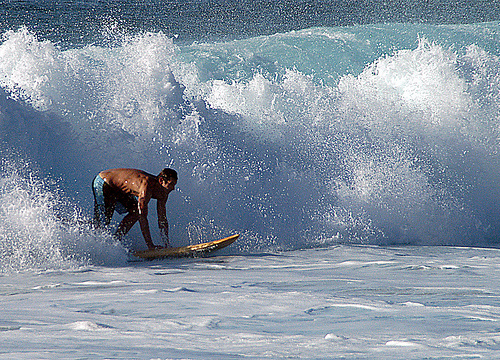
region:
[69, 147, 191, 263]
surfer in black and blue shorts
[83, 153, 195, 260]
a shirtless man surfing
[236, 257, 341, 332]
white ocean foam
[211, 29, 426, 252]
a wave in the ocean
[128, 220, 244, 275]
a tan colored surfboard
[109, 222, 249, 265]
a surfer with his hands on the board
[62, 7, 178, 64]
the splash of an ocean wave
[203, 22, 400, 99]
light teal colored ocean wave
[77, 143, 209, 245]
a tan skinned surfer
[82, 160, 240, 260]
surfing in the ocean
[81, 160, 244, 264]
Surfer in the sea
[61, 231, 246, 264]
Surf board in sea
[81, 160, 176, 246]
Surfer with blue short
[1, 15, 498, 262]
Big wave in the sea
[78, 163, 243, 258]
Crouched surfer in a big wave.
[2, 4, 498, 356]
Sea water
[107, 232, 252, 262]
Orange and yellow surfboard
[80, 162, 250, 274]
Surfer on a surfboard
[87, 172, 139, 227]
Blue short wet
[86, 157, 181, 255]
Surfer without top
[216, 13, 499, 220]
blue and white breaking wave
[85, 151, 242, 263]
surfer riding a wave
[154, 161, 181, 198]
black haired surfer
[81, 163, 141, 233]
blue and black board shorts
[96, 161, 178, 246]
surfer with tan skin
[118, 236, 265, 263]
yellow surf board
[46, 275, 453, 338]
ocean foam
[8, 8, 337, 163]
white ocean spash from a wave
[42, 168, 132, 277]
tan surfer getting splashed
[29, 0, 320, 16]
dark blue ocean behind the wave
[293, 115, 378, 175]
spray from waves in the air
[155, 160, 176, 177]
man has dark hair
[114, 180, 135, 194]
man's ribs are visible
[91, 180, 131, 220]
man is wearing blue shorts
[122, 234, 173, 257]
man's hands are on surfboard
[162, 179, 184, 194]
man appears to be looking ahead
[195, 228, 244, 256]
surfboard curves upward in the front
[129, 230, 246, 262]
surfboard is yellow and black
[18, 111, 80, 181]
part of the wave is in shadow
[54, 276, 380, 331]
small waves on surface of water